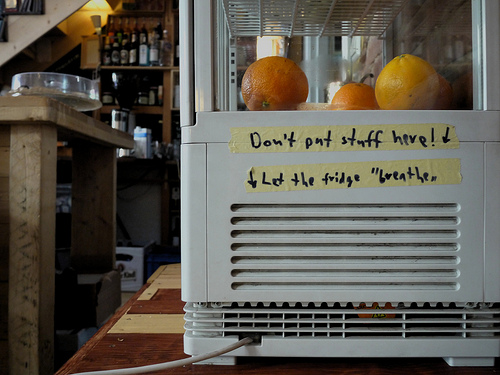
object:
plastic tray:
[11, 72, 103, 112]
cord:
[70, 337, 256, 375]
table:
[1, 97, 134, 375]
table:
[51, 264, 499, 375]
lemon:
[375, 53, 453, 110]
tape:
[245, 157, 463, 194]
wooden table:
[55, 262, 500, 375]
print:
[245, 165, 438, 188]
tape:
[229, 124, 460, 153]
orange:
[241, 55, 309, 110]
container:
[180, 0, 499, 369]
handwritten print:
[250, 127, 450, 149]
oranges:
[240, 53, 453, 109]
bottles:
[138, 33, 149, 65]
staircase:
[0, 0, 90, 68]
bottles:
[103, 36, 112, 65]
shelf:
[94, 10, 173, 143]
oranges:
[330, 82, 380, 111]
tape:
[228, 124, 464, 194]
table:
[57, 264, 500, 375]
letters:
[246, 127, 450, 149]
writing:
[246, 166, 437, 190]